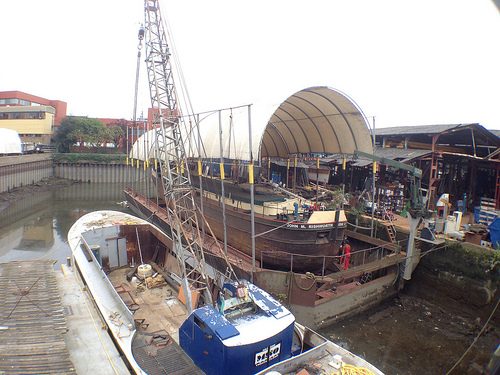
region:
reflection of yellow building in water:
[20, 203, 57, 280]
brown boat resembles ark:
[168, 173, 328, 298]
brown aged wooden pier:
[42, 269, 82, 349]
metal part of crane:
[137, 13, 198, 187]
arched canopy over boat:
[223, 90, 348, 186]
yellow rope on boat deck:
[334, 363, 349, 369]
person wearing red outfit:
[338, 235, 358, 298]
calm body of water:
[53, 184, 96, 229]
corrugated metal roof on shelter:
[432, 113, 474, 168]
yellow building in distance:
[10, 113, 47, 139]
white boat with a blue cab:
[61, 200, 356, 371]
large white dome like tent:
[141, 95, 376, 170]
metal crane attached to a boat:
[134, 7, 235, 301]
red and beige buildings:
[0, 87, 74, 140]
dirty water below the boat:
[12, 198, 95, 263]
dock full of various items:
[389, 177, 495, 251]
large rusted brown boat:
[158, 155, 358, 276]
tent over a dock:
[371, 120, 490, 218]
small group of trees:
[51, 110, 128, 156]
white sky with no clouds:
[53, 7, 437, 109]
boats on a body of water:
[3, 2, 497, 374]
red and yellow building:
[5, 86, 177, 158]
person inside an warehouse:
[427, 180, 465, 227]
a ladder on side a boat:
[375, 208, 409, 256]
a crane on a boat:
[68, 0, 309, 370]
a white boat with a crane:
[65, 201, 362, 372]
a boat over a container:
[130, 71, 407, 316]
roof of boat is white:
[126, 78, 380, 186]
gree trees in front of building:
[53, 112, 125, 161]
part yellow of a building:
[1, 109, 58, 141]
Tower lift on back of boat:
[125, 5, 236, 253]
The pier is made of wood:
[12, 266, 67, 371]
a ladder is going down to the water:
[373, 200, 424, 267]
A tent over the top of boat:
[182, 103, 369, 178]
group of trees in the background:
[41, 110, 142, 163]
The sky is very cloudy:
[30, 43, 137, 109]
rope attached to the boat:
[275, 253, 349, 309]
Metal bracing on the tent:
[284, 90, 364, 137]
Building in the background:
[385, 108, 497, 187]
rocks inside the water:
[407, 294, 498, 354]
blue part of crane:
[173, 271, 301, 369]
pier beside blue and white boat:
[2, 253, 105, 374]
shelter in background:
[376, 118, 494, 236]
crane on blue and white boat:
[140, 5, 225, 298]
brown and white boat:
[165, 155, 345, 256]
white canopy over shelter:
[131, 88, 383, 166]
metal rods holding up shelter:
[131, 149, 376, 261]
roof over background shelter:
[372, 113, 489, 175]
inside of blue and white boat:
[110, 231, 204, 343]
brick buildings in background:
[0, 88, 179, 158]